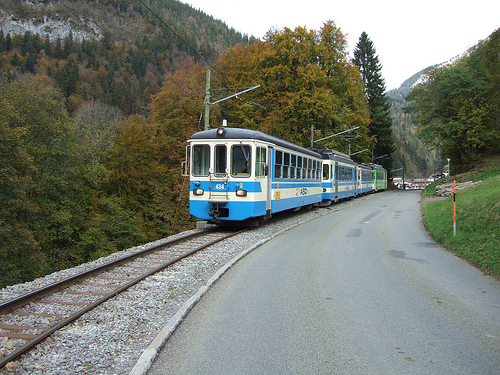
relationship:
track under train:
[0, 218, 219, 373] [173, 113, 412, 234]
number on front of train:
[215, 184, 224, 190] [179, 115, 392, 233]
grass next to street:
[419, 170, 498, 276] [140, 188, 498, 373]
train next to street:
[179, 115, 392, 233] [140, 188, 498, 373]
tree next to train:
[3, 71, 108, 268] [179, 115, 392, 233]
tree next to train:
[1, 119, 52, 281] [179, 115, 392, 233]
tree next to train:
[101, 109, 183, 231] [179, 115, 392, 233]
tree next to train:
[158, 52, 228, 235] [179, 115, 392, 233]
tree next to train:
[233, 24, 375, 158] [179, 115, 392, 233]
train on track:
[179, 119, 389, 233] [0, 224, 240, 373]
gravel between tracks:
[0, 229, 220, 373] [0, 224, 244, 366]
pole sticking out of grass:
[444, 164, 498, 248] [432, 181, 483, 228]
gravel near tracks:
[6, 197, 349, 371] [0, 224, 244, 366]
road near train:
[147, 185, 498, 373] [154, 102, 394, 258]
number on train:
[212, 180, 226, 193] [179, 115, 392, 233]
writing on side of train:
[298, 183, 308, 196] [179, 115, 392, 233]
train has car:
[179, 115, 392, 233] [370, 163, 390, 192]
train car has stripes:
[181, 116, 324, 232] [249, 180, 325, 205]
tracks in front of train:
[4, 217, 254, 373] [179, 115, 392, 233]